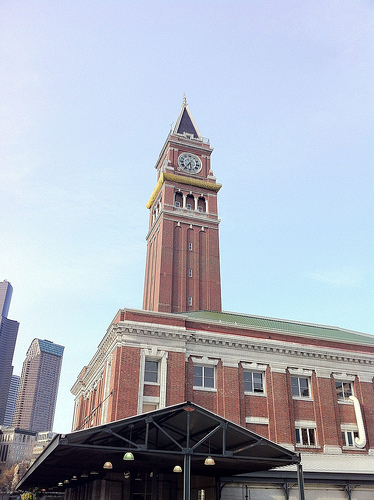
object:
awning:
[14, 400, 301, 491]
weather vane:
[183, 92, 187, 105]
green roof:
[175, 311, 374, 346]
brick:
[274, 394, 277, 397]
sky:
[0, 0, 374, 432]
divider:
[155, 178, 203, 190]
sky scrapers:
[0, 278, 65, 434]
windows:
[283, 367, 289, 449]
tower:
[142, 93, 221, 313]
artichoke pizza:
[17, 255, 60, 333]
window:
[332, 371, 355, 406]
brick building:
[70, 84, 371, 497]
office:
[12, 338, 66, 432]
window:
[241, 362, 267, 398]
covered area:
[14, 400, 301, 491]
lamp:
[204, 456, 216, 465]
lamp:
[173, 465, 183, 472]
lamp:
[123, 452, 134, 461]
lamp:
[103, 462, 113, 470]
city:
[0, 95, 374, 499]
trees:
[13, 491, 47, 498]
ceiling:
[16, 399, 300, 492]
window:
[295, 420, 322, 449]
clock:
[177, 152, 202, 175]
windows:
[197, 193, 208, 213]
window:
[144, 360, 159, 382]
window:
[191, 356, 217, 392]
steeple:
[172, 92, 203, 142]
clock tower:
[142, 93, 222, 313]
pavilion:
[14, 400, 305, 500]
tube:
[349, 395, 367, 448]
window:
[288, 368, 314, 402]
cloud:
[23, 254, 88, 300]